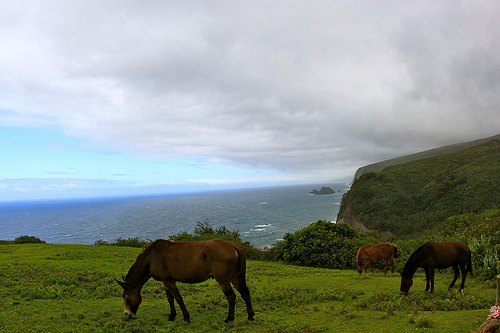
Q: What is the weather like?
A: It is stormy.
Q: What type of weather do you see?
A: It is stormy.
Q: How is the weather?
A: It is stormy.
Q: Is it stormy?
A: Yes, it is stormy.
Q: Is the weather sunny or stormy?
A: It is stormy.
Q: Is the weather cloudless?
A: No, it is stormy.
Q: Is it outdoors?
A: Yes, it is outdoors.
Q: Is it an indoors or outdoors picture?
A: It is outdoors.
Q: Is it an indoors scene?
A: No, it is outdoors.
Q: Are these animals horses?
A: Yes, all the animals are horses.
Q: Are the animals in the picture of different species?
A: No, all the animals are horses.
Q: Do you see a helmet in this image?
A: No, there are no helmets.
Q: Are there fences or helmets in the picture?
A: No, there are no helmets or fences.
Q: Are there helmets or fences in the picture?
A: No, there are no helmets or fences.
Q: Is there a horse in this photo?
A: Yes, there is a horse.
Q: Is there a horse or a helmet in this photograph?
A: Yes, there is a horse.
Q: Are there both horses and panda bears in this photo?
A: No, there is a horse but no panda bears.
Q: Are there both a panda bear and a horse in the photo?
A: No, there is a horse but no panda bears.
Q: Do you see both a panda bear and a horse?
A: No, there is a horse but no panda bears.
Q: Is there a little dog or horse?
A: Yes, there is a little horse.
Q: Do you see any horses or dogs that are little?
A: Yes, the horse is little.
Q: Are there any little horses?
A: Yes, there is a little horse.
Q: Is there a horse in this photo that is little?
A: Yes, there is a horse that is little.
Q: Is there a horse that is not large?
A: Yes, there is a little horse.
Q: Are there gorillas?
A: No, there are no gorillas.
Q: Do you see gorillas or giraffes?
A: No, there are no gorillas or giraffes.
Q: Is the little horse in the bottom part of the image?
A: Yes, the horse is in the bottom of the image.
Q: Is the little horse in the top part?
A: No, the horse is in the bottom of the image.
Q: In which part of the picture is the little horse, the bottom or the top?
A: The horse is in the bottom of the image.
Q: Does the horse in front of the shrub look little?
A: Yes, the horse is little.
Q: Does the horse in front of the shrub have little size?
A: Yes, the horse is little.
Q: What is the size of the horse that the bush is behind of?
A: The horse is little.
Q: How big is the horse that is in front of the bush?
A: The horse is little.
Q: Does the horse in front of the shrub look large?
A: No, the horse is little.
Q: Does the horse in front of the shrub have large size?
A: No, the horse is little.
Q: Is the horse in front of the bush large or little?
A: The horse is little.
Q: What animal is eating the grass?
A: The horse is eating the grass.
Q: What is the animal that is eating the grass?
A: The animal is a horse.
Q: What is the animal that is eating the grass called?
A: The animal is a horse.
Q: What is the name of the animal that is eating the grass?
A: The animal is a horse.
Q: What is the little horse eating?
A: The horse is eating grass.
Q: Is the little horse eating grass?
A: Yes, the horse is eating grass.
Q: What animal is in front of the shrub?
A: The horse is in front of the shrub.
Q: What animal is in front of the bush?
A: The horse is in front of the shrub.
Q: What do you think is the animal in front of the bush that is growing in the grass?
A: The animal is a horse.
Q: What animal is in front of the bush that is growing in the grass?
A: The animal is a horse.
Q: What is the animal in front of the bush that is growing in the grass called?
A: The animal is a horse.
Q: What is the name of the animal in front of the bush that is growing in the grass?
A: The animal is a horse.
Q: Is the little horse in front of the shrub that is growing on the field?
A: Yes, the horse is in front of the bush.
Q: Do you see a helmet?
A: No, there are no helmets.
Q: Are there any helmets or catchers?
A: No, there are no helmets or catchers.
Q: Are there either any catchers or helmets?
A: No, there are no helmets or catchers.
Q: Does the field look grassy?
A: Yes, the field is grassy.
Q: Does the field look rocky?
A: No, the field is grassy.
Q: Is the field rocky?
A: No, the field is grassy.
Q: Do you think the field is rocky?
A: No, the field is grassy.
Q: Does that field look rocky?
A: No, the field is grassy.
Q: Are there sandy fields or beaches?
A: No, there is a field but it is grassy.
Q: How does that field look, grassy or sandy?
A: The field is grassy.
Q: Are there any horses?
A: Yes, there is a horse.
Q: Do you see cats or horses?
A: Yes, there is a horse.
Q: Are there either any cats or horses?
A: Yes, there is a horse.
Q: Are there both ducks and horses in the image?
A: No, there is a horse but no ducks.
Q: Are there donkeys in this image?
A: No, there are no donkeys.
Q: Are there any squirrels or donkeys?
A: No, there are no donkeys or squirrels.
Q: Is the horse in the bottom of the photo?
A: Yes, the horse is in the bottom of the image.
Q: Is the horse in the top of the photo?
A: No, the horse is in the bottom of the image.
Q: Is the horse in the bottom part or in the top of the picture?
A: The horse is in the bottom of the image.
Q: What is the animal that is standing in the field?
A: The animal is a horse.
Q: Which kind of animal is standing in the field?
A: The animal is a horse.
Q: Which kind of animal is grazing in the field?
A: The animal is a horse.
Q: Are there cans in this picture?
A: No, there are no cans.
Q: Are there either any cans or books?
A: No, there are no cans or books.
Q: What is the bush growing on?
A: The bush is growing on the field.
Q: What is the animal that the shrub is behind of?
A: The animal is a horse.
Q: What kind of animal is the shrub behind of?
A: The shrub is behind the horse.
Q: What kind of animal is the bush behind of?
A: The shrub is behind the horse.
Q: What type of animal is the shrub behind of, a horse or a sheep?
A: The shrub is behind a horse.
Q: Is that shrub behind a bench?
A: No, the shrub is behind a horse.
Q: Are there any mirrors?
A: No, there are no mirrors.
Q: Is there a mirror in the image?
A: No, there are no mirrors.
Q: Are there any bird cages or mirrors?
A: No, there are no mirrors or bird cages.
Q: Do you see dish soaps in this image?
A: No, there are no dish soaps.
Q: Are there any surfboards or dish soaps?
A: No, there are no dish soaps or surfboards.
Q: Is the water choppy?
A: Yes, the water is choppy.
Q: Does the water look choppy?
A: Yes, the water is choppy.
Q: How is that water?
A: The water is choppy.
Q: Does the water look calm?
A: No, the water is choppy.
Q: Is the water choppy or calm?
A: The water is choppy.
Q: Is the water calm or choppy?
A: The water is choppy.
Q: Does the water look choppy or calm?
A: The water is choppy.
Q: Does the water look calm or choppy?
A: The water is choppy.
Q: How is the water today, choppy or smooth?
A: The water is choppy.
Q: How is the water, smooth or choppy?
A: The water is choppy.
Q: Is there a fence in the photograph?
A: No, there are no fences.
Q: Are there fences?
A: No, there are no fences.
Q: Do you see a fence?
A: No, there are no fences.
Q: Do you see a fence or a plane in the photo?
A: No, there are no fences or airplanes.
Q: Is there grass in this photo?
A: Yes, there is grass.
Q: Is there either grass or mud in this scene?
A: Yes, there is grass.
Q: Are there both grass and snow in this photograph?
A: No, there is grass but no snow.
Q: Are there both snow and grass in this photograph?
A: No, there is grass but no snow.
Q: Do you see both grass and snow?
A: No, there is grass but no snow.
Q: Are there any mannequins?
A: No, there are no mannequins.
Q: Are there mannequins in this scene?
A: No, there are no mannequins.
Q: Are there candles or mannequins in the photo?
A: No, there are no mannequins or candles.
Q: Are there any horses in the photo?
A: Yes, there is a horse.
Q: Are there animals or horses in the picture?
A: Yes, there is a horse.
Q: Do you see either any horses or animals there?
A: Yes, there is a horse.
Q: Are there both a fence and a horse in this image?
A: No, there is a horse but no fences.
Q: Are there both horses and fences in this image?
A: No, there is a horse but no fences.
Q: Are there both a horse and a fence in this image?
A: No, there is a horse but no fences.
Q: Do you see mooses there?
A: No, there are no mooses.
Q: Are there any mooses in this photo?
A: No, there are no mooses.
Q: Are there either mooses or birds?
A: No, there are no mooses or birds.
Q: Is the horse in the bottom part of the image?
A: Yes, the horse is in the bottom of the image.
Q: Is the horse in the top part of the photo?
A: No, the horse is in the bottom of the image.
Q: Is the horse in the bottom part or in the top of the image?
A: The horse is in the bottom of the image.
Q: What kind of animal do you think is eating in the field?
A: The animal is a horse.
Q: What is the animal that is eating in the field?
A: The animal is a horse.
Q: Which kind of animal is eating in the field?
A: The animal is a horse.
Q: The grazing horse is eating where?
A: The horse is eating in the field.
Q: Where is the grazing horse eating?
A: The horse is eating in the field.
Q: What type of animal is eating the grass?
A: The animal is a horse.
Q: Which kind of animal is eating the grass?
A: The animal is a horse.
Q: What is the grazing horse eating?
A: The horse is eating grass.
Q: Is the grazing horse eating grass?
A: Yes, the horse is eating grass.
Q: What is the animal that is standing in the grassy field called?
A: The animal is a horse.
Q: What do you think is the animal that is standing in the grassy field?
A: The animal is a horse.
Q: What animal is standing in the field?
A: The animal is a horse.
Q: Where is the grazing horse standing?
A: The horse is standing in the field.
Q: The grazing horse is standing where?
A: The horse is standing in the field.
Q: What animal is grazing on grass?
A: The horse is grazing on grass.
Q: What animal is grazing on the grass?
A: The horse is grazing on grass.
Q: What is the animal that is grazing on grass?
A: The animal is a horse.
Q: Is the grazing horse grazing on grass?
A: Yes, the horse is grazing on grass.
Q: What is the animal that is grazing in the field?
A: The animal is a horse.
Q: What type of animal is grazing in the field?
A: The animal is a horse.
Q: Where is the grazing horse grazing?
A: The horse is grazing in the field.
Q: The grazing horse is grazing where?
A: The horse is grazing in the field.